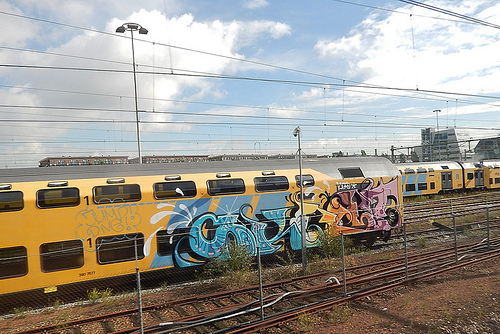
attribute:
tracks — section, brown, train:
[231, 251, 443, 293]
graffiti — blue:
[172, 202, 302, 269]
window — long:
[88, 173, 140, 213]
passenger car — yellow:
[460, 159, 499, 188]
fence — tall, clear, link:
[95, 240, 485, 301]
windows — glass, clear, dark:
[1, 175, 318, 202]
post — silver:
[251, 242, 266, 322]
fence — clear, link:
[70, 210, 494, 330]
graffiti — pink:
[351, 176, 402, 233]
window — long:
[93, 232, 146, 263]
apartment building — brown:
[41, 154, 132, 167]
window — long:
[207, 180, 244, 195]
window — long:
[205, 177, 249, 197]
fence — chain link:
[211, 211, 498, 296]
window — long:
[150, 179, 196, 201]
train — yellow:
[0, 153, 404, 310]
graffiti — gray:
[76, 195, 143, 251]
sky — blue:
[1, 2, 484, 167]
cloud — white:
[18, 8, 245, 136]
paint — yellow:
[0, 167, 360, 296]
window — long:
[0, 242, 31, 283]